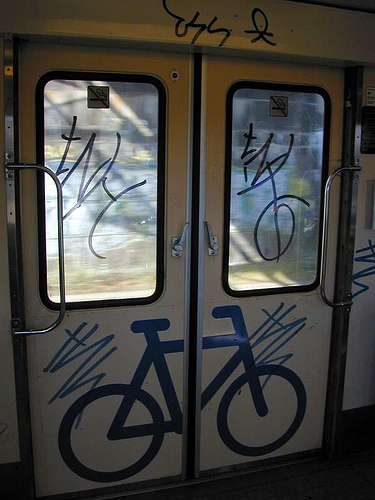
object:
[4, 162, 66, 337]
doorhandlebar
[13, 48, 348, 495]
door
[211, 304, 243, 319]
handle bar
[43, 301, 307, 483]
clipart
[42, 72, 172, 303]
window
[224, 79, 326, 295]
window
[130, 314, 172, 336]
seat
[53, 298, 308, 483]
bicycle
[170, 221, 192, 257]
handle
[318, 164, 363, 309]
handle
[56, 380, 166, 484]
wheel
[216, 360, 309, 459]
wheel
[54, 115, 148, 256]
doodles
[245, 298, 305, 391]
doodles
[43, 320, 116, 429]
doodles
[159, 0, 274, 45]
doodles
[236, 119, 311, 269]
doodles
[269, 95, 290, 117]
label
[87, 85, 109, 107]
label